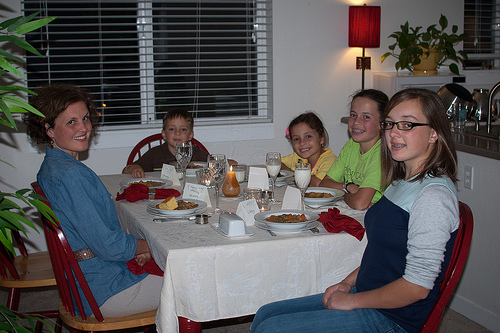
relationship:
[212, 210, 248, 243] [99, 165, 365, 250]
butter dish on table top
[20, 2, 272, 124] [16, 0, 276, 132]
gray blinds on window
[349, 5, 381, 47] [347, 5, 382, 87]
red lampshade on lamp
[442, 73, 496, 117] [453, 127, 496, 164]
pots on countertop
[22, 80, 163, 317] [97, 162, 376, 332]
person sitting at dining table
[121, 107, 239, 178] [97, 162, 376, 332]
boy sitting at dining table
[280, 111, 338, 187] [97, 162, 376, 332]
girl sitting at dining table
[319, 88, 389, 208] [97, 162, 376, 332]
person sitting at dining table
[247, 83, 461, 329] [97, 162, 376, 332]
person sitting at dining table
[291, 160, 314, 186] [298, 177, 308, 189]
glass of milk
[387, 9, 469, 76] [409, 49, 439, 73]
plant in pot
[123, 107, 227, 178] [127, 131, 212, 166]
boy sitting on chair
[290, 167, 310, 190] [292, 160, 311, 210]
milk in whole glass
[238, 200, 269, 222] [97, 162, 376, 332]
card on dining table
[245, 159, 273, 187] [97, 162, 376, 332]
card on dining table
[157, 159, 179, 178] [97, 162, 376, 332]
card on dining table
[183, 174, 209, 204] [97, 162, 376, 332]
card on dining table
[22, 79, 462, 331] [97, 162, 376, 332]
group sitting at dining table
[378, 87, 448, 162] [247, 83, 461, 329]
head of person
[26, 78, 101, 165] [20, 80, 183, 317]
head of person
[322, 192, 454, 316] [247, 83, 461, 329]
arm of person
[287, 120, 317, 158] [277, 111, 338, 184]
face of girl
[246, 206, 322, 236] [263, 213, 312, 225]
white bowl of food